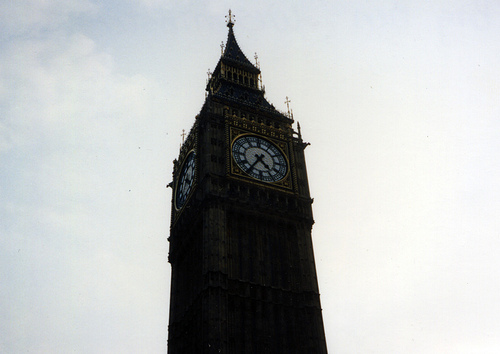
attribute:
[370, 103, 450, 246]
sky — hazy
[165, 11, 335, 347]
tower — dark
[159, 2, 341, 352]
clock tower — tall 